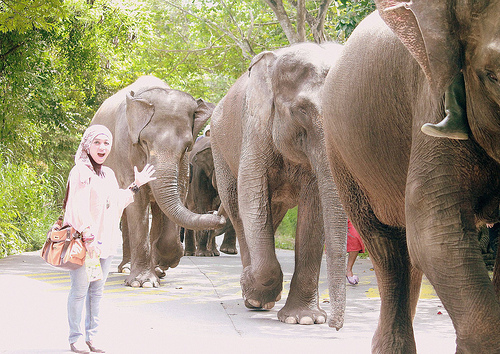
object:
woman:
[41, 124, 158, 354]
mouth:
[95, 149, 108, 158]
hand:
[133, 164, 164, 185]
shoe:
[85, 329, 106, 352]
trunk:
[307, 156, 353, 330]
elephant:
[209, 39, 350, 324]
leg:
[216, 169, 284, 310]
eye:
[296, 97, 308, 114]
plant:
[0, 0, 59, 257]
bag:
[39, 219, 92, 270]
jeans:
[66, 263, 109, 333]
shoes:
[71, 334, 92, 354]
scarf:
[71, 123, 115, 182]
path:
[99, 168, 224, 282]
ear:
[242, 51, 279, 138]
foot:
[236, 246, 285, 312]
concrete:
[153, 254, 260, 322]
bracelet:
[127, 181, 147, 196]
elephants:
[317, 0, 500, 353]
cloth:
[346, 213, 365, 254]